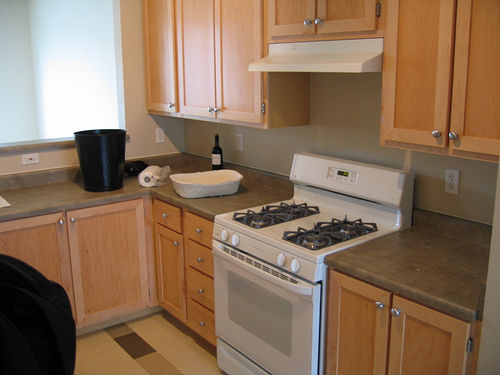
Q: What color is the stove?
A: White.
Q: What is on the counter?
A: A bottle of wine.